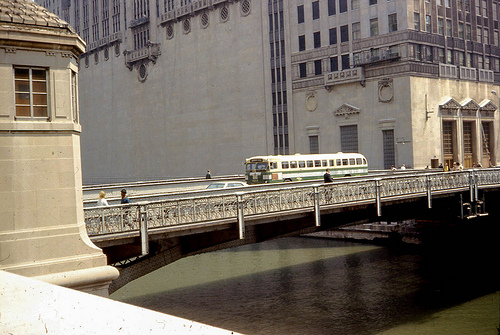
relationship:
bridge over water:
[145, 180, 423, 212] [272, 269, 409, 310]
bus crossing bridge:
[230, 144, 373, 181] [145, 180, 423, 212]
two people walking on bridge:
[85, 183, 141, 214] [145, 180, 423, 212]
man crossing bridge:
[319, 168, 337, 188] [145, 180, 423, 212]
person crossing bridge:
[201, 168, 214, 180] [145, 180, 423, 212]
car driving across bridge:
[204, 179, 246, 190] [145, 180, 423, 212]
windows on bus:
[283, 158, 366, 170] [230, 144, 373, 181]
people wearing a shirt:
[391, 162, 483, 171] [443, 165, 448, 171]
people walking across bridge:
[389, 159, 499, 175] [145, 180, 423, 212]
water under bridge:
[272, 269, 409, 310] [145, 180, 423, 212]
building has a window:
[4, 4, 88, 193] [290, 3, 309, 24]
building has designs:
[4, 4, 88, 193] [165, 8, 249, 27]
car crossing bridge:
[204, 179, 246, 190] [145, 180, 423, 212]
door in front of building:
[441, 120, 458, 174] [4, 4, 88, 193]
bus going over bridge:
[230, 144, 373, 181] [145, 180, 423, 212]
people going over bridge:
[389, 159, 499, 175] [145, 180, 423, 212]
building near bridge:
[4, 4, 88, 193] [145, 180, 423, 212]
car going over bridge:
[206, 181, 248, 189] [145, 180, 423, 212]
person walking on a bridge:
[201, 168, 214, 180] [145, 180, 423, 212]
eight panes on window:
[17, 66, 51, 117] [290, 3, 309, 24]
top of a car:
[217, 179, 241, 184] [204, 179, 246, 190]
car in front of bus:
[204, 179, 246, 190] [230, 144, 373, 181]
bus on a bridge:
[230, 144, 373, 181] [145, 180, 423, 212]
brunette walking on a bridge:
[453, 160, 465, 172] [145, 180, 423, 212]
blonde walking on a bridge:
[98, 188, 106, 197] [145, 180, 423, 212]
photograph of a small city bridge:
[4, 3, 497, 333] [166, 186, 387, 207]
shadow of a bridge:
[363, 230, 402, 263] [145, 180, 423, 212]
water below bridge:
[272, 269, 409, 310] [145, 180, 423, 212]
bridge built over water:
[145, 180, 423, 212] [272, 269, 409, 310]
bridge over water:
[145, 180, 423, 212] [140, 214, 480, 330]